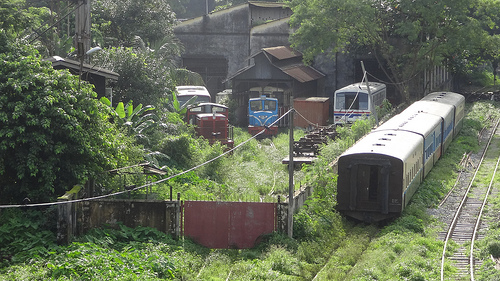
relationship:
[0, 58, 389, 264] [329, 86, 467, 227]
fence near train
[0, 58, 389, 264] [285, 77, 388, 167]
fence near train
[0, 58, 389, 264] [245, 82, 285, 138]
fence near train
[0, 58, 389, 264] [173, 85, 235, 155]
fence near train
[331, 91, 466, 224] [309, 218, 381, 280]
car on track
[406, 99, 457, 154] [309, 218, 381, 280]
car on track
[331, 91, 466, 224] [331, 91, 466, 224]
car on car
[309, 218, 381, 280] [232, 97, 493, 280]
track in grass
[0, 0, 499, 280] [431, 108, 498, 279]
train yard has tracks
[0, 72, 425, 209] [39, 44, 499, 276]
electrical lines around train yard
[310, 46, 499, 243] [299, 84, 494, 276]
train on track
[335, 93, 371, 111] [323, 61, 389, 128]
window on train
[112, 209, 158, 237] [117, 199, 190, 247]
moss on wall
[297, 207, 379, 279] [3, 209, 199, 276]
rail lines on grass